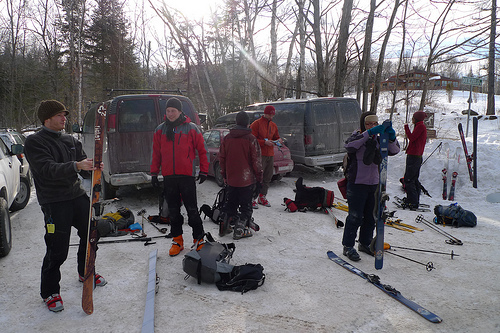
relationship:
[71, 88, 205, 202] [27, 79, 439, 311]
van behind skiers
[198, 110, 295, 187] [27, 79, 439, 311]
vehicle behind skiers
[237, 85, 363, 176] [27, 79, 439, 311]
vehicle behind skiers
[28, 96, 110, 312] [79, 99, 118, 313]
skier holds ski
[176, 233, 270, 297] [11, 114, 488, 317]
bag on ground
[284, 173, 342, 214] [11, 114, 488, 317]
bag on ground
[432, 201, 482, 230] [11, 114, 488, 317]
bag on ground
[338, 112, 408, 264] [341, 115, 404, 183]
skier has jacket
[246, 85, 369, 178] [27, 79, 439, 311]
van behind skiers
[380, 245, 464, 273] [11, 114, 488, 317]
poles on ground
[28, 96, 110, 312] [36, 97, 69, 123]
skier wears hat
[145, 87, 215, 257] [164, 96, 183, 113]
skier wears hat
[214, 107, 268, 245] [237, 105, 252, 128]
skier wears hat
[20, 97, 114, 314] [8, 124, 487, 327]
man standing on snow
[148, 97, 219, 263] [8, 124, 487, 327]
person standing on snow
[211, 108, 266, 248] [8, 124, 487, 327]
person standing on snow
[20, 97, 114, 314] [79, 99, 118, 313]
man holding ski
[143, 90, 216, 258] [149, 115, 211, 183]
man in jacket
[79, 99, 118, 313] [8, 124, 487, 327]
ski on snow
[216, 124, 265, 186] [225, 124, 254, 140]
jacket has hood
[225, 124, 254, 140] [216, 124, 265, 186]
hood on jacket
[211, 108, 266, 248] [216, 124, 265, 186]
person has jacket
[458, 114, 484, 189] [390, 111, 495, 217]
skis in snowbank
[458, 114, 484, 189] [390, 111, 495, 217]
skis stuck in snowbank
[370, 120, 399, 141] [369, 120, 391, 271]
hands on skis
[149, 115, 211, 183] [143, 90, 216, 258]
jacket worn by man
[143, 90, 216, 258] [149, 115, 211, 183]
man wearing jacket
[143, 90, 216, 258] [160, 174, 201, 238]
man wearing pants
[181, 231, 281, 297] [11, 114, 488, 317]
backpack on ground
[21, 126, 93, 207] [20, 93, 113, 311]
jacket worn by man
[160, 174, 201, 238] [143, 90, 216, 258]
pants worn by man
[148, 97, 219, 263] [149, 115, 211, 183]
person wearing jacket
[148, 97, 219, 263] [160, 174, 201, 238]
person wearing pants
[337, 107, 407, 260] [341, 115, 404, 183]
person wearing jacket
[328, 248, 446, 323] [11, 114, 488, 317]
ski on ground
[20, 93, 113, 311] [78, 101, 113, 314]
man holding ski equipment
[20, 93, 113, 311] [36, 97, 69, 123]
man wearing hat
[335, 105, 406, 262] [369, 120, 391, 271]
man holding ski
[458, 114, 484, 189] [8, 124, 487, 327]
skis sitting in snow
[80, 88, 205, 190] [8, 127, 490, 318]
van in lot